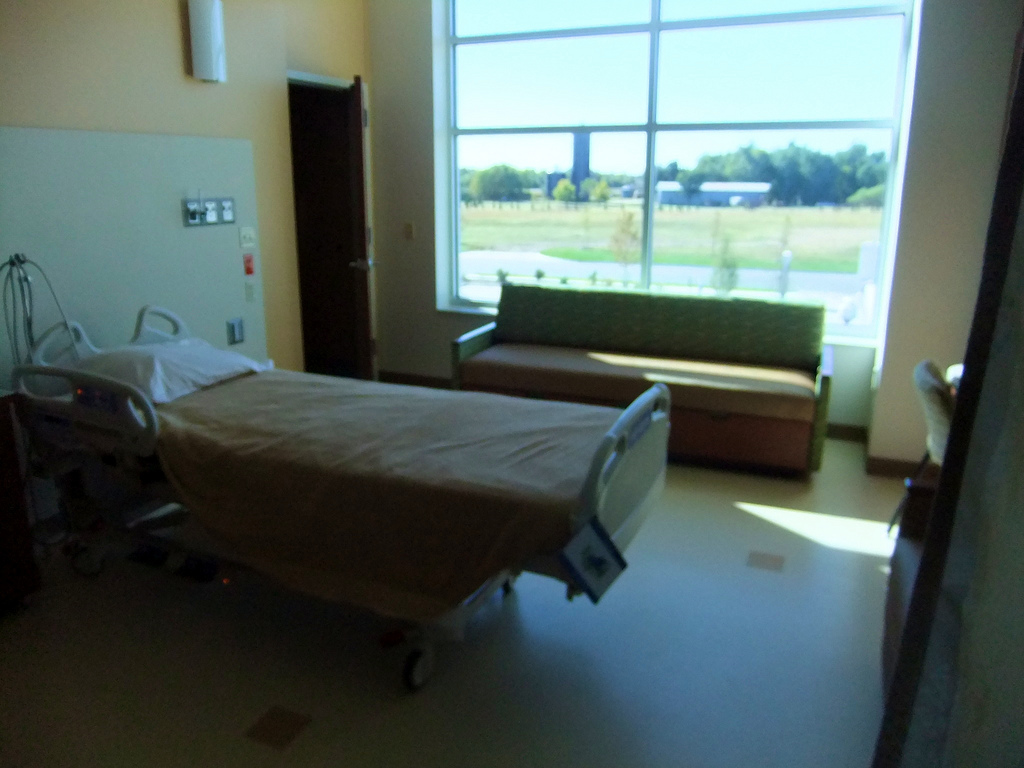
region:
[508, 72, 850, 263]
See through glass window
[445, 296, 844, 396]
Brown couch on bedside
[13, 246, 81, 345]
Gadgets hanging from wall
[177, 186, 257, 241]
Buttons placed on wall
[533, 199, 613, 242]
Green grass on field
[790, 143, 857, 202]
Thick green bushy shrubs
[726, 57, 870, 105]
Clear blue cloudless sky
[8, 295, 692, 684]
The empty hospital bed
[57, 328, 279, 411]
The white pillow on the bed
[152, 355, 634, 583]
The brown blanket on the bed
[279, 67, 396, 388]
The open door to a dark room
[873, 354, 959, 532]
The back of a desk chair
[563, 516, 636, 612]
The chart at the foot of the bed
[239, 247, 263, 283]
The red square panel near the door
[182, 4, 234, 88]
The white rectangular light on the wall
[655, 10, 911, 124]
window panel is clean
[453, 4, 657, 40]
window panel is clean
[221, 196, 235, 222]
outlet is metal and clean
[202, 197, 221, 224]
outlet is metal and clean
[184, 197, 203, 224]
outlet is metal and clean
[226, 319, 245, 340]
outlet is metal and clean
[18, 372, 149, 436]
railing for hospital bed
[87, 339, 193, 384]
pillow on hospital bed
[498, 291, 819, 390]
couch in hospital room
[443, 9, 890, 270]
large window in room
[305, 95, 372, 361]
doorway into the bathroom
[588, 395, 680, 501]
foot rail for bed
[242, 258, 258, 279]
red emergency button for patient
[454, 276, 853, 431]
Green and brown couch in front of window.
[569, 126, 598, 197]
Silo outside by farm.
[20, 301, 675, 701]
Bed in hospital room.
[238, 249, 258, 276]
Emergency switch on wall.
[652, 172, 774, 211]
Barn outside window near silos.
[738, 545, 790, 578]
Brown square tile in floor.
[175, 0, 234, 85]
Light on wall above bed.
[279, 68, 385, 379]
Half open door in room.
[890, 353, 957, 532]
Chair pushed up next to desk.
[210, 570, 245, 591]
Red dot on floor under bed.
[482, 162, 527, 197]
A tree in the woods.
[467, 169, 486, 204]
A tree in the woods.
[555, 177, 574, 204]
A tree in the woods.